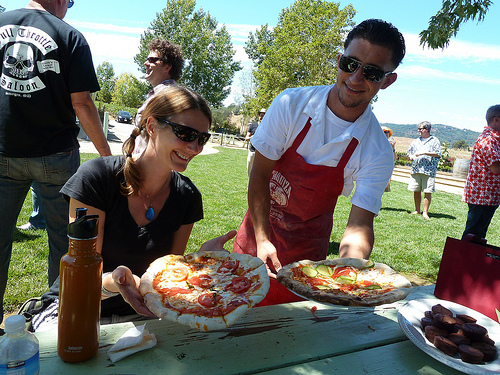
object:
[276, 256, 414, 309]
pizza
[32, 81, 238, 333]
woman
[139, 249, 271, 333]
pizza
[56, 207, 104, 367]
container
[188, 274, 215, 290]
tomato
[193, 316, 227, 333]
crust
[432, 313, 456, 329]
brownies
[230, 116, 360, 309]
apron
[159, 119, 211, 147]
glass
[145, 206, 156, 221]
gem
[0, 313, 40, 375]
water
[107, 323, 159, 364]
napkin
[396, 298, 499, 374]
plate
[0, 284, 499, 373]
table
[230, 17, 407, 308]
man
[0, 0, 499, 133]
sky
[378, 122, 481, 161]
mountains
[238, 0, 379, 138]
tree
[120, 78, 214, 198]
hair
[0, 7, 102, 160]
shirt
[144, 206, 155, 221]
blue